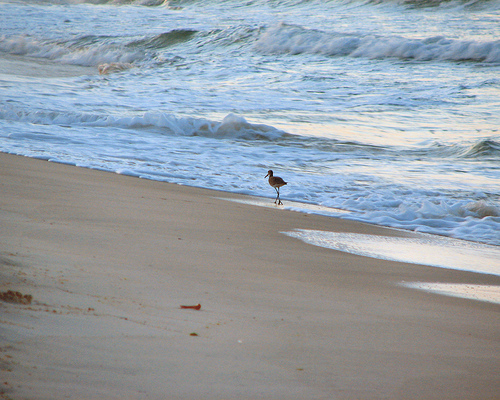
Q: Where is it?
A: This is at the ocean.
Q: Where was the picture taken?
A: It was taken at the ocean.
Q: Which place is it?
A: It is an ocean.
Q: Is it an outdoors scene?
A: Yes, it is outdoors.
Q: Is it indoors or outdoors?
A: It is outdoors.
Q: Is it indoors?
A: No, it is outdoors.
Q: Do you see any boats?
A: No, there are no boats.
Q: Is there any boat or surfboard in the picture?
A: No, there are no boats or surfboards.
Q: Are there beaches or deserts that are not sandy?
A: No, there is a beach but it is sandy.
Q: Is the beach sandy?
A: Yes, the beach is sandy.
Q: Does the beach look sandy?
A: Yes, the beach is sandy.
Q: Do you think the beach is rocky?
A: No, the beach is sandy.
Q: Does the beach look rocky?
A: No, the beach is sandy.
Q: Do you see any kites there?
A: No, there are no kites.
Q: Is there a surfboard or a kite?
A: No, there are no kites or surfboards.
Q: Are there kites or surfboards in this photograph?
A: No, there are no kites or surfboards.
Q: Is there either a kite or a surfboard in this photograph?
A: No, there are no kites or surfboards.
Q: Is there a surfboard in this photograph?
A: No, there are no surfboards.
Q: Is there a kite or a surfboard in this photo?
A: No, there are no surfboards or kites.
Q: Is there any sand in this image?
A: Yes, there is sand.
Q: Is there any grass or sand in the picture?
A: Yes, there is sand.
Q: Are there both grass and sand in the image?
A: No, there is sand but no grass.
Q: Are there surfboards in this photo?
A: No, there are no surfboards.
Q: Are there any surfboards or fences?
A: No, there are no surfboards or fences.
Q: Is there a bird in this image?
A: Yes, there is a bird.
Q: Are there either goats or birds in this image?
A: Yes, there is a bird.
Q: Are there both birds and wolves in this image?
A: No, there is a bird but no wolves.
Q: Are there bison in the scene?
A: No, there are no bison.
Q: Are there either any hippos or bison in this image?
A: No, there are no bison or hippos.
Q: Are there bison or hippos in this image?
A: No, there are no bison or hippos.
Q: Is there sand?
A: Yes, there is sand.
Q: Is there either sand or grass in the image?
A: Yes, there is sand.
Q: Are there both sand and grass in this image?
A: No, there is sand but no grass.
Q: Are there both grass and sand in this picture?
A: No, there is sand but no grass.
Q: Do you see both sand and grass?
A: No, there is sand but no grass.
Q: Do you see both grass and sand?
A: No, there is sand but no grass.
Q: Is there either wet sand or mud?
A: Yes, there is wet sand.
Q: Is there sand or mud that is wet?
A: Yes, the sand is wet.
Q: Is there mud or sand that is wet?
A: Yes, the sand is wet.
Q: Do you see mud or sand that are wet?
A: Yes, the sand is wet.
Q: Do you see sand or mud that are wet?
A: Yes, the sand is wet.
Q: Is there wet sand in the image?
A: Yes, there is wet sand.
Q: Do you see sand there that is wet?
A: Yes, there is sand that is wet.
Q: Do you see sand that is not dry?
A: Yes, there is wet sand.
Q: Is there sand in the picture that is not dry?
A: Yes, there is wet sand.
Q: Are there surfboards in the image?
A: No, there are no surfboards.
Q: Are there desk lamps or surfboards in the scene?
A: No, there are no surfboards or desk lamps.